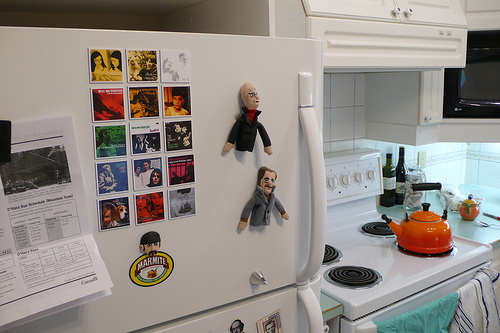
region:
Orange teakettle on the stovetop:
[381, 178, 463, 259]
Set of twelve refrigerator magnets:
[84, 43, 209, 234]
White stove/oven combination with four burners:
[316, 142, 494, 332]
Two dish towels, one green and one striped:
[372, 267, 499, 330]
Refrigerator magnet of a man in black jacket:
[214, 81, 281, 164]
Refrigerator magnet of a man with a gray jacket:
[231, 161, 295, 238]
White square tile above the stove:
[324, 74, 366, 151]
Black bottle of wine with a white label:
[395, 143, 412, 207]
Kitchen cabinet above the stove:
[305, 1, 474, 26]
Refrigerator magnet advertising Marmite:
[122, 229, 184, 291]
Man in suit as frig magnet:
[216, 79, 278, 166]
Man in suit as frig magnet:
[236, 165, 294, 237]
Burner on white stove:
[326, 264, 384, 291]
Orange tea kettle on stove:
[381, 182, 461, 259]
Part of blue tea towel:
[393, 316, 442, 330]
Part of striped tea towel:
[460, 287, 496, 327]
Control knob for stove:
[336, 171, 356, 190]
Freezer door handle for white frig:
[293, 67, 333, 288]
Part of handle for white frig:
[288, 285, 324, 328]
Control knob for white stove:
[366, 168, 376, 182]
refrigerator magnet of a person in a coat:
[227, 161, 298, 250]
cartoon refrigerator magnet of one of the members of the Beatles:
[133, 228, 168, 258]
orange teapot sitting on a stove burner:
[368, 178, 464, 266]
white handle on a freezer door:
[293, 68, 329, 286]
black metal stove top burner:
[323, 263, 383, 290]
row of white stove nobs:
[324, 156, 379, 198]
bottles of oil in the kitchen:
[380, 143, 407, 207]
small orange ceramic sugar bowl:
[458, 193, 485, 226]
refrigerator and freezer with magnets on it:
[0, 25, 325, 330]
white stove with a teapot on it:
[321, 147, 497, 330]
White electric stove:
[308, 148, 483, 330]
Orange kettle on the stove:
[382, 179, 469, 264]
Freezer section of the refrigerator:
[0, 23, 332, 330]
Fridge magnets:
[220, 78, 301, 249]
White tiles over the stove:
[323, 74, 385, 155]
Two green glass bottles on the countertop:
[381, 139, 411, 207]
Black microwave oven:
[444, 35, 498, 122]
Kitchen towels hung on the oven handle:
[373, 253, 493, 330]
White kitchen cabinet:
[299, 2, 465, 37]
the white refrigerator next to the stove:
[0, 25, 323, 331]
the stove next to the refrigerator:
[318, 146, 491, 331]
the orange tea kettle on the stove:
[379, 182, 453, 252]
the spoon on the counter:
[476, 219, 498, 228]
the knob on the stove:
[327, 174, 339, 187]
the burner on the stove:
[322, 263, 383, 288]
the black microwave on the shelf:
[444, 42, 499, 117]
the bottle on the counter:
[381, 151, 396, 205]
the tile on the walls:
[323, 71, 498, 188]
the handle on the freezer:
[297, 72, 324, 286]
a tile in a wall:
[330, 70, 357, 104]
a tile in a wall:
[476, 158, 498, 188]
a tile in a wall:
[330, 105, 355, 141]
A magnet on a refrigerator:
[130, 230, 175, 286]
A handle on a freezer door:
[296, 73, 328, 289]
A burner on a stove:
[325, 262, 378, 289]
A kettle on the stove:
[378, 181, 458, 256]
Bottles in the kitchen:
[383, 146, 405, 208]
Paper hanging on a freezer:
[1, 116, 113, 332]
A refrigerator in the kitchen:
[2, 25, 325, 332]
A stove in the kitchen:
[319, 150, 489, 332]